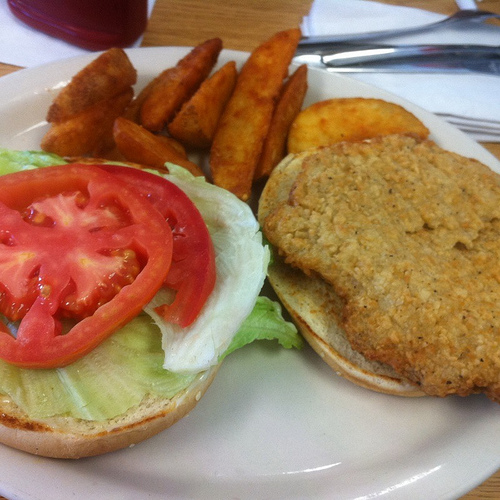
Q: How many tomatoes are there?
A: Two.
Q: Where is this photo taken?
A: At a table.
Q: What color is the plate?
A: White.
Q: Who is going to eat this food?
A: A man or woman.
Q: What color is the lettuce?
A: Green.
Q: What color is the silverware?
A: Gray.